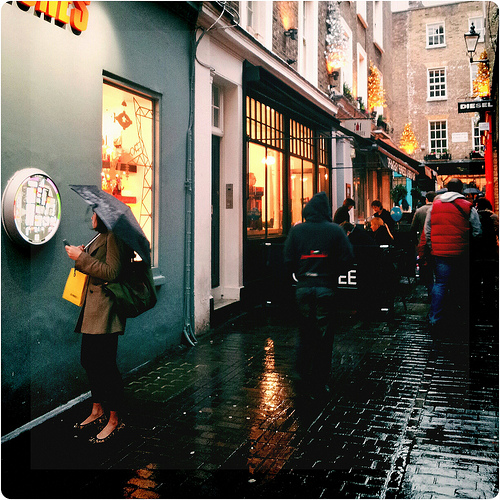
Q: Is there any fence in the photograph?
A: No, there are no fences.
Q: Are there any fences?
A: No, there are no fences.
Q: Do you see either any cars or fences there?
A: No, there are no fences or cars.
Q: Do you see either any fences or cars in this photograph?
A: No, there are no fences or cars.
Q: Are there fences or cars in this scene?
A: No, there are no fences or cars.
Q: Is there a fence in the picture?
A: No, there are no fences.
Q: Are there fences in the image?
A: No, there are no fences.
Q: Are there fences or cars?
A: No, there are no fences or cars.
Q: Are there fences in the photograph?
A: No, there are no fences.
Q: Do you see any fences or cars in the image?
A: No, there are no fences or cars.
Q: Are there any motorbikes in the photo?
A: No, there are no motorbikes.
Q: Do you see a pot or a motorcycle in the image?
A: No, there are no motorcycles or pots.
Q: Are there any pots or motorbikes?
A: No, there are no motorbikes or pots.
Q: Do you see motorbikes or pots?
A: No, there are no motorbikes or pots.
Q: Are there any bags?
A: Yes, there is a bag.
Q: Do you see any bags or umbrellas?
A: Yes, there is a bag.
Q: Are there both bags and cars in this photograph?
A: No, there is a bag but no cars.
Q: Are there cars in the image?
A: No, there are no cars.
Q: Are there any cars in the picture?
A: No, there are no cars.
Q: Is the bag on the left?
A: Yes, the bag is on the left of the image.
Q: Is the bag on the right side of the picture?
A: No, the bag is on the left of the image.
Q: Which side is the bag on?
A: The bag is on the left of the image.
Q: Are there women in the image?
A: Yes, there is a woman.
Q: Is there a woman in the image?
A: Yes, there is a woman.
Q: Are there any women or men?
A: Yes, there is a woman.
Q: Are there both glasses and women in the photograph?
A: No, there is a woman but no glasses.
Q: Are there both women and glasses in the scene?
A: No, there is a woman but no glasses.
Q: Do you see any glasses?
A: No, there are no glasses.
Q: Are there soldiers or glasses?
A: No, there are no glasses or soldiers.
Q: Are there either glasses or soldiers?
A: No, there are no glasses or soldiers.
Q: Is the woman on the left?
A: Yes, the woman is on the left of the image.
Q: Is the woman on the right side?
A: No, the woman is on the left of the image.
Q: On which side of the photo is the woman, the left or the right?
A: The woman is on the left of the image.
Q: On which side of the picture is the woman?
A: The woman is on the left of the image.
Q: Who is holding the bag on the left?
A: The woman is holding the bag.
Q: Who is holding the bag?
A: The woman is holding the bag.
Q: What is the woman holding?
A: The woman is holding the bag.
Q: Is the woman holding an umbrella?
A: No, the woman is holding the bag.